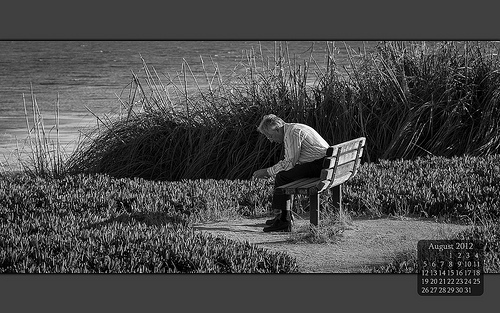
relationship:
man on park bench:
[249, 112, 334, 238] [274, 133, 371, 237]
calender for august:
[414, 236, 488, 299] [424, 241, 476, 253]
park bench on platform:
[274, 133, 371, 237] [190, 201, 492, 273]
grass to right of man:
[13, 32, 500, 175] [249, 112, 334, 238]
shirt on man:
[266, 120, 332, 177] [249, 112, 334, 238]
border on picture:
[0, 37, 499, 278] [2, 1, 498, 310]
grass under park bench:
[282, 194, 357, 246] [274, 133, 371, 237]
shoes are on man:
[260, 213, 295, 236] [249, 112, 334, 238]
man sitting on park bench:
[249, 112, 334, 238] [274, 133, 371, 237]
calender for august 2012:
[414, 236, 488, 299] [423, 241, 479, 253]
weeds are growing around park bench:
[288, 200, 356, 246] [274, 133, 371, 237]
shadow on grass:
[75, 191, 266, 246] [3, 154, 500, 272]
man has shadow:
[249, 112, 334, 238] [75, 191, 266, 246]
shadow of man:
[75, 191, 266, 246] [249, 112, 334, 238]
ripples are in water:
[31, 73, 113, 90] [0, 39, 499, 173]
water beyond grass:
[0, 39, 499, 173] [3, 154, 500, 272]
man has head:
[249, 112, 334, 238] [255, 109, 286, 148]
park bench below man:
[274, 133, 371, 237] [249, 112, 334, 238]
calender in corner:
[414, 236, 488, 299] [390, 234, 500, 311]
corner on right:
[390, 234, 500, 311] [360, 0, 500, 312]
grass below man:
[3, 154, 500, 272] [249, 112, 334, 238]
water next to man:
[0, 39, 499, 173] [249, 112, 334, 238]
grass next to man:
[13, 32, 500, 175] [249, 112, 334, 238]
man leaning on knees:
[249, 112, 334, 238] [272, 167, 295, 193]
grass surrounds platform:
[3, 154, 500, 272] [190, 201, 492, 273]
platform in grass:
[190, 201, 492, 273] [3, 154, 500, 272]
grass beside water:
[3, 154, 500, 272] [0, 39, 499, 173]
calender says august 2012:
[414, 236, 488, 299] [423, 241, 479, 253]